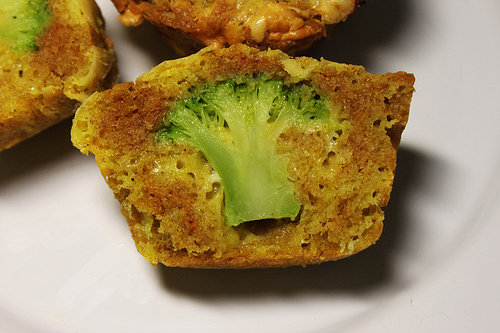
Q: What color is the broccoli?
A: Green.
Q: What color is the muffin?
A: Brown.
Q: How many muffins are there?
A: Three.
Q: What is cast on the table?
A: Shadow.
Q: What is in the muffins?
A: Broccoli.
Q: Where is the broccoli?
A: In the muffins.